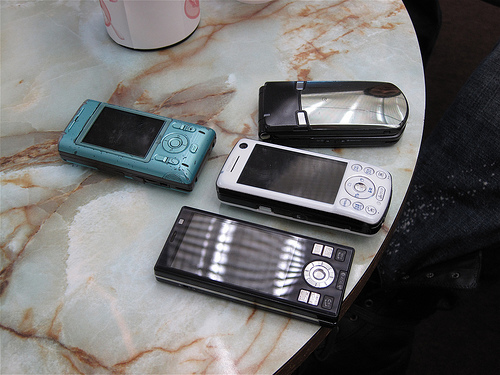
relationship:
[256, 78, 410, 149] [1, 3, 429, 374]
cell phone on table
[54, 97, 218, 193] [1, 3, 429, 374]
camera on table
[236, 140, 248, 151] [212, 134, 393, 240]
camera on front of cell phone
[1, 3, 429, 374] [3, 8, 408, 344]
table has design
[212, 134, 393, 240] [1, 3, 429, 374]
cell phone on table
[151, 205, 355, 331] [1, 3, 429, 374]
cell phone on table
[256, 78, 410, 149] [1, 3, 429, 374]
cell phone on top of table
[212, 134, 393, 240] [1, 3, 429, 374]
cell phone on top of table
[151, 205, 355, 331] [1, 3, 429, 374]
cell phone on top of table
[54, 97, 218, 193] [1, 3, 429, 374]
camera on top of table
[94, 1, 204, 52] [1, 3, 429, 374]
cup on table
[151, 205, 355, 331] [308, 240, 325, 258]
cell phone has button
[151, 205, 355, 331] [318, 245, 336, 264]
cell phone has button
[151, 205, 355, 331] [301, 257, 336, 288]
cell phone has button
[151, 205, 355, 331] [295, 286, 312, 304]
cell phone has button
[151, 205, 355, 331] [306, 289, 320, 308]
cell phone has button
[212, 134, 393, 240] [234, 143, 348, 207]
cell phone has screen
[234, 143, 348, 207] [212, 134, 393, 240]
screen on cell phone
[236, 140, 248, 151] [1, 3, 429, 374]
camera on table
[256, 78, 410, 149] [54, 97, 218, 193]
cell phone with camera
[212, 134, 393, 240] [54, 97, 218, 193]
cell phone with camera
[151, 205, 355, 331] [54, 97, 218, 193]
cell phone with camera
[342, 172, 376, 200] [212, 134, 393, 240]
control on cell phone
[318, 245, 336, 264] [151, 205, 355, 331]
button on cell phone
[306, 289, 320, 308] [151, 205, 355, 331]
button on cell phone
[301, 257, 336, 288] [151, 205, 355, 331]
button on cell phone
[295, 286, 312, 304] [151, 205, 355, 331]
button on cell phone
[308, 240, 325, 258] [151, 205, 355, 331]
button on cell phone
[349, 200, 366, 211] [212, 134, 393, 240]
button on cell phone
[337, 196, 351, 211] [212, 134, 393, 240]
button on cell phone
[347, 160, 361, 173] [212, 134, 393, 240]
button on cell phone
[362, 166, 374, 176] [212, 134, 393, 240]
button on cell phone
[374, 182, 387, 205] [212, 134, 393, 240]
button on cell phone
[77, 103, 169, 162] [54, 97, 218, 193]
screen on camera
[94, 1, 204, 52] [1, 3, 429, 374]
cup sitting on table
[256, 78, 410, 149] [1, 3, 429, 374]
cell phone sitting on table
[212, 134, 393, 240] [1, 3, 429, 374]
cell phone sitting on table